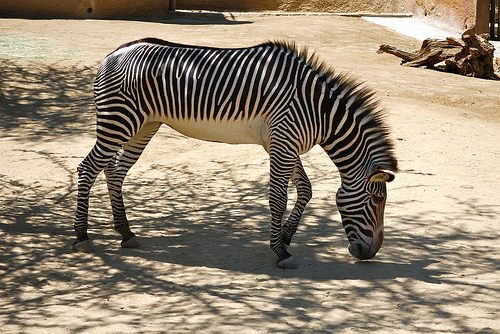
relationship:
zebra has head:
[74, 37, 399, 270] [336, 157, 396, 263]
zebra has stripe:
[74, 37, 399, 270] [255, 45, 286, 115]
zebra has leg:
[74, 37, 399, 270] [270, 133, 301, 270]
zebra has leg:
[74, 37, 399, 270] [74, 103, 147, 253]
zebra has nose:
[74, 37, 399, 270] [347, 241, 380, 259]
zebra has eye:
[74, 37, 399, 270] [373, 193, 387, 204]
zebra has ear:
[74, 37, 399, 270] [368, 168, 395, 184]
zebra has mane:
[74, 37, 399, 270] [272, 38, 398, 175]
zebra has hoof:
[74, 37, 399, 270] [121, 234, 142, 247]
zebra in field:
[74, 37, 399, 270] [0, 11, 499, 334]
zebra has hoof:
[74, 37, 399, 270] [276, 255, 297, 268]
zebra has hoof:
[74, 37, 399, 270] [283, 241, 289, 249]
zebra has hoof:
[74, 37, 399, 270] [75, 240, 93, 253]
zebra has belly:
[74, 37, 399, 270] [159, 118, 269, 145]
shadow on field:
[0, 56, 499, 330] [0, 11, 499, 334]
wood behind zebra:
[377, 25, 499, 81] [74, 37, 399, 270]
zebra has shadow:
[74, 37, 399, 270] [353, 259, 453, 284]